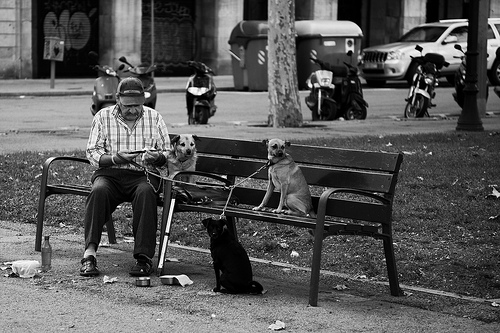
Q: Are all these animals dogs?
A: Yes, all the animals are dogs.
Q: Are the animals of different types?
A: No, all the animals are dogs.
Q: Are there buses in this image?
A: No, there are no buses.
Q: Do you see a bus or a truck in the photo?
A: No, there are no buses or trucks.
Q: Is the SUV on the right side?
A: Yes, the SUV is on the right of the image.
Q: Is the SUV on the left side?
A: No, the SUV is on the right of the image.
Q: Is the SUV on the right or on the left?
A: The SUV is on the right of the image.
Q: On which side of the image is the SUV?
A: The SUV is on the right of the image.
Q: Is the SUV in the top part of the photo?
A: Yes, the SUV is in the top of the image.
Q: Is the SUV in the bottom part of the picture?
A: No, the SUV is in the top of the image.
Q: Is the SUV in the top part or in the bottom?
A: The SUV is in the top of the image.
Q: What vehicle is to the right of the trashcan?
A: The vehicle is a SUV.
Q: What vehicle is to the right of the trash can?
A: The vehicle is a SUV.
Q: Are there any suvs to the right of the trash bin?
A: Yes, there is a SUV to the right of the trash bin.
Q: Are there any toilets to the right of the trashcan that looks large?
A: No, there is a SUV to the right of the garbage bin.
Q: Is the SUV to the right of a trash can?
A: Yes, the SUV is to the right of a trash can.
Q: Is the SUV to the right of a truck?
A: No, the SUV is to the right of a trash can.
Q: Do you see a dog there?
A: Yes, there is a dog.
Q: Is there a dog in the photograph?
A: Yes, there is a dog.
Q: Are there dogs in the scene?
A: Yes, there is a dog.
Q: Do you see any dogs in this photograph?
A: Yes, there is a dog.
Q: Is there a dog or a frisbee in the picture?
A: Yes, there is a dog.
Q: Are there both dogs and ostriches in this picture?
A: No, there is a dog but no ostriches.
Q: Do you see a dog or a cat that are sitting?
A: Yes, the dog is sitting.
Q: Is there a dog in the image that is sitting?
A: Yes, there is a dog that is sitting.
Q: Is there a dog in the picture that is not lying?
A: Yes, there is a dog that is sitting.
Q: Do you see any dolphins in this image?
A: No, there are no dolphins.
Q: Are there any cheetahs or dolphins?
A: No, there are no dolphins or cheetahs.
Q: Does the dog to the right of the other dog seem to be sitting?
A: Yes, the dog is sitting.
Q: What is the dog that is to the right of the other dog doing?
A: The dog is sitting.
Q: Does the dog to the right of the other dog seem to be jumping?
A: No, the dog is sitting.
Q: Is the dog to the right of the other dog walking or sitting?
A: The dog is sitting.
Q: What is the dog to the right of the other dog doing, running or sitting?
A: The dog is sitting.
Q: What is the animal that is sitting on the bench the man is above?
A: The animal is a dog.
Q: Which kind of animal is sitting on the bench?
A: The animal is a dog.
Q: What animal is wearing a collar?
A: The dog is wearing a collar.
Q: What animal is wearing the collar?
A: The dog is wearing a collar.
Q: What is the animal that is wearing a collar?
A: The animal is a dog.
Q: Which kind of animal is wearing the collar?
A: The animal is a dog.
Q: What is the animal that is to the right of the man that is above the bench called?
A: The animal is a dog.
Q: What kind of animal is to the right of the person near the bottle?
A: The animal is a dog.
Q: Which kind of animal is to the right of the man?
A: The animal is a dog.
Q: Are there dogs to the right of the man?
A: Yes, there is a dog to the right of the man.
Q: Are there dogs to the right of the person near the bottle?
A: Yes, there is a dog to the right of the man.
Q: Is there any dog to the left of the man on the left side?
A: No, the dog is to the right of the man.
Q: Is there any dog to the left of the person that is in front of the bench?
A: No, the dog is to the right of the man.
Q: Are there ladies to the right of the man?
A: No, there is a dog to the right of the man.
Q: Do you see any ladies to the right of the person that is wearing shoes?
A: No, there is a dog to the right of the man.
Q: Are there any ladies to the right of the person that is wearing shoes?
A: No, there is a dog to the right of the man.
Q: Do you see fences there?
A: No, there are no fences.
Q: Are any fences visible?
A: No, there are no fences.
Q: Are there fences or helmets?
A: No, there are no fences or helmets.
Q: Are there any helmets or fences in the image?
A: No, there are no fences or helmets.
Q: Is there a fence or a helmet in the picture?
A: No, there are no fences or helmets.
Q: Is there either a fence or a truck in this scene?
A: No, there are no fences or trucks.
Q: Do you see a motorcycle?
A: Yes, there is a motorcycle.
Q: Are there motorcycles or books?
A: Yes, there is a motorcycle.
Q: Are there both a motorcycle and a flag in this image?
A: No, there is a motorcycle but no flags.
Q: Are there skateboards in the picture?
A: No, there are no skateboards.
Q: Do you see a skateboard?
A: No, there are no skateboards.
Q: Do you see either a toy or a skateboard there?
A: No, there are no skateboards or toys.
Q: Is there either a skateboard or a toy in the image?
A: No, there are no skateboards or toys.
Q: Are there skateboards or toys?
A: No, there are no skateboards or toys.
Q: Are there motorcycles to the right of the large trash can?
A: Yes, there is a motorcycle to the right of the garbage can.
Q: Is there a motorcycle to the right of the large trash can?
A: Yes, there is a motorcycle to the right of the garbage can.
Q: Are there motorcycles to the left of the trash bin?
A: No, the motorcycle is to the right of the trash bin.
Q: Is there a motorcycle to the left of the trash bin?
A: No, the motorcycle is to the right of the trash bin.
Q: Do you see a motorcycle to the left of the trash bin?
A: No, the motorcycle is to the right of the trash bin.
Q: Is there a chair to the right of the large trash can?
A: No, there is a motorcycle to the right of the garbage bin.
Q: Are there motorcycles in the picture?
A: Yes, there is a motorcycle.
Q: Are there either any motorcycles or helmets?
A: Yes, there is a motorcycle.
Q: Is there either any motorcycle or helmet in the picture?
A: Yes, there is a motorcycle.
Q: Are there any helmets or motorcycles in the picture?
A: Yes, there is a motorcycle.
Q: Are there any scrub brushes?
A: No, there are no scrub brushes.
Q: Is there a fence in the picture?
A: No, there are no fences.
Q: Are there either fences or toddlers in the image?
A: No, there are no fences or toddlers.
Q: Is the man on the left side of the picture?
A: Yes, the man is on the left of the image.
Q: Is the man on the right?
A: No, the man is on the left of the image.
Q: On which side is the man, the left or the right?
A: The man is on the left of the image.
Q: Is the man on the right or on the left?
A: The man is on the left of the image.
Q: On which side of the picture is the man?
A: The man is on the left of the image.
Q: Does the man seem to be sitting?
A: Yes, the man is sitting.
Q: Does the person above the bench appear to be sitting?
A: Yes, the man is sitting.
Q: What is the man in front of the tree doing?
A: The man is sitting.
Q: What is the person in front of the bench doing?
A: The man is sitting.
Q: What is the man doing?
A: The man is sitting.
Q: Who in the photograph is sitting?
A: The man is sitting.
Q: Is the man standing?
A: No, the man is sitting.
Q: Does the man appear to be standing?
A: No, the man is sitting.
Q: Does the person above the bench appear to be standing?
A: No, the man is sitting.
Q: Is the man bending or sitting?
A: The man is sitting.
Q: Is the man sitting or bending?
A: The man is sitting.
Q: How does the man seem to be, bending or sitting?
A: The man is sitting.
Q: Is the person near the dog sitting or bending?
A: The man is sitting.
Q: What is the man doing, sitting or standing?
A: The man is sitting.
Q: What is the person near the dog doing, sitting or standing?
A: The man is sitting.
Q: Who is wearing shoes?
A: The man is wearing shoes.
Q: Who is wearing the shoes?
A: The man is wearing shoes.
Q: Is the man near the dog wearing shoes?
A: Yes, the man is wearing shoes.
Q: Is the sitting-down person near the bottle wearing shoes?
A: Yes, the man is wearing shoes.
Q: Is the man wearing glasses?
A: No, the man is wearing shoes.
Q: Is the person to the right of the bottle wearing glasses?
A: No, the man is wearing shoes.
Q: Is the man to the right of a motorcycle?
A: No, the man is to the left of a motorcycle.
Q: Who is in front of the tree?
A: The man is in front of the tree.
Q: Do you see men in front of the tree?
A: Yes, there is a man in front of the tree.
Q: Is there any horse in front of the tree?
A: No, there is a man in front of the tree.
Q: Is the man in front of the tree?
A: Yes, the man is in front of the tree.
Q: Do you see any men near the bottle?
A: Yes, there is a man near the bottle.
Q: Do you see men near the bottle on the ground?
A: Yes, there is a man near the bottle.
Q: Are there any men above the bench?
A: Yes, there is a man above the bench.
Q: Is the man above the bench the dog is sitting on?
A: Yes, the man is above the bench.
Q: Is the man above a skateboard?
A: No, the man is above the bench.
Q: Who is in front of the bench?
A: The man is in front of the bench.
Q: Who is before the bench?
A: The man is in front of the bench.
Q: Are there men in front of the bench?
A: Yes, there is a man in front of the bench.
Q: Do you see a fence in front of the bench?
A: No, there is a man in front of the bench.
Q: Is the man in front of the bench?
A: Yes, the man is in front of the bench.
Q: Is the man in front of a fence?
A: No, the man is in front of the bench.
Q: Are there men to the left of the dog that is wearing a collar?
A: Yes, there is a man to the left of the dog.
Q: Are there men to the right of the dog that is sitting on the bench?
A: No, the man is to the left of the dog.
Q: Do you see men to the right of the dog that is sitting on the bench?
A: No, the man is to the left of the dog.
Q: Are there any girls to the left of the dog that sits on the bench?
A: No, there is a man to the left of the dog.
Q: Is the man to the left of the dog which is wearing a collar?
A: Yes, the man is to the left of the dog.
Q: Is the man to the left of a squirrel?
A: No, the man is to the left of the dog.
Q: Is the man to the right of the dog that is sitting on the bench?
A: No, the man is to the left of the dog.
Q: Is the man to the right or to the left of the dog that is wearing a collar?
A: The man is to the left of the dog.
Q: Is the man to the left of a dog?
A: Yes, the man is to the left of a dog.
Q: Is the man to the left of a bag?
A: No, the man is to the left of a dog.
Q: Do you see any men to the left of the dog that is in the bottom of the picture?
A: Yes, there is a man to the left of the dog.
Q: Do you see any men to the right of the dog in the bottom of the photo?
A: No, the man is to the left of the dog.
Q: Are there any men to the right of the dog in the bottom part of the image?
A: No, the man is to the left of the dog.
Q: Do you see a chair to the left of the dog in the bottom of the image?
A: No, there is a man to the left of the dog.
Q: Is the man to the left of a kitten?
A: No, the man is to the left of a dog.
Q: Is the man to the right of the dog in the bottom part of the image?
A: No, the man is to the left of the dog.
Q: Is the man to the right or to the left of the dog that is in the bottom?
A: The man is to the left of the dog.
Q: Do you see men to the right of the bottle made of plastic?
A: Yes, there is a man to the right of the bottle.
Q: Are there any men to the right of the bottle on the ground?
A: Yes, there is a man to the right of the bottle.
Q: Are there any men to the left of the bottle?
A: No, the man is to the right of the bottle.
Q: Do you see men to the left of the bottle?
A: No, the man is to the right of the bottle.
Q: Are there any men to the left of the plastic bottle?
A: No, the man is to the right of the bottle.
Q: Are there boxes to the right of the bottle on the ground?
A: No, there is a man to the right of the bottle.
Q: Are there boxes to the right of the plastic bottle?
A: No, there is a man to the right of the bottle.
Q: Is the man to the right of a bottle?
A: Yes, the man is to the right of a bottle.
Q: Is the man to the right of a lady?
A: No, the man is to the right of a bottle.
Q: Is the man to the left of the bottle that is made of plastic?
A: No, the man is to the right of the bottle.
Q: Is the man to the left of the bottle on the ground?
A: No, the man is to the right of the bottle.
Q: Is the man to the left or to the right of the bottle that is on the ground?
A: The man is to the right of the bottle.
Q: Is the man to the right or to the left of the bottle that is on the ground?
A: The man is to the right of the bottle.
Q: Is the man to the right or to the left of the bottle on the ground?
A: The man is to the right of the bottle.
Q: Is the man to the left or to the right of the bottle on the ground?
A: The man is to the right of the bottle.